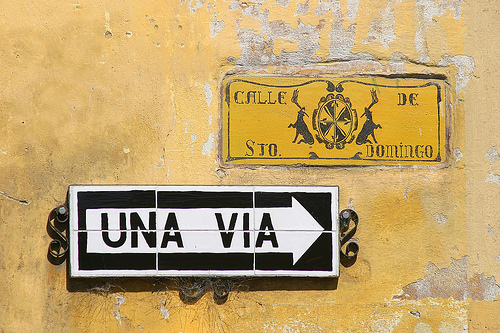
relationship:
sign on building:
[223, 69, 452, 163] [2, 4, 500, 331]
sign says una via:
[65, 184, 339, 281] [98, 204, 285, 255]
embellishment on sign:
[342, 209, 360, 264] [65, 184, 339, 281]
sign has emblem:
[223, 69, 452, 163] [286, 82, 386, 149]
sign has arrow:
[65, 184, 339, 281] [88, 196, 328, 264]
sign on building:
[65, 184, 339, 281] [2, 4, 500, 331]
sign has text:
[223, 69, 452, 163] [240, 134, 282, 160]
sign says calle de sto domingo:
[223, 69, 452, 163] [236, 88, 433, 161]